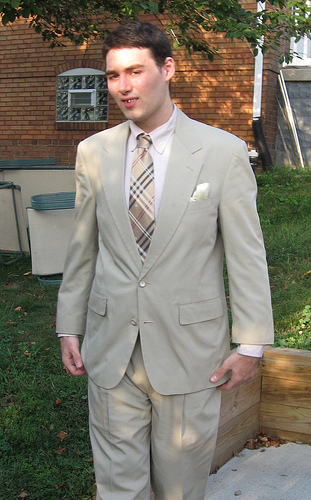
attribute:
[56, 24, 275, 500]
man — young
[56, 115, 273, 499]
suit — tan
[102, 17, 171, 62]
his hair — brown, short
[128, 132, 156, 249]
tie — plaid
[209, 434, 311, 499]
ground — cement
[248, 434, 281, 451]
leaves — dead, brown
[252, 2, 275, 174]
gutters — black, white, metal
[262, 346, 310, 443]
wood — wooden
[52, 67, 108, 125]
window — glass block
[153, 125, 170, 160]
shirt — white, dress shirt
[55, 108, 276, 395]
jacket — tan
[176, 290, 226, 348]
pocket — off white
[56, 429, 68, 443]
leaves — brown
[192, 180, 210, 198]
handkerchief — white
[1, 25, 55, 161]
brick — red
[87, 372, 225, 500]
pants — tan, light colored